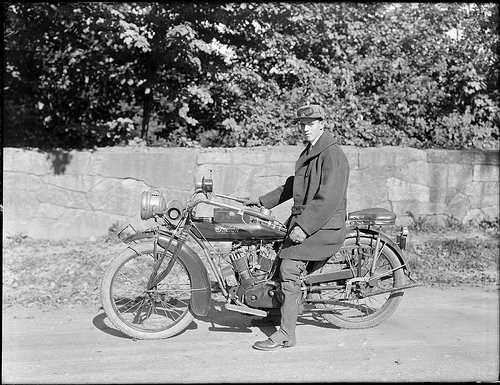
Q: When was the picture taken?
A: Daytime.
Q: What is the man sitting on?
A: A motorcycle.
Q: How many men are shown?
A: One.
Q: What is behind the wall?
A: Trees.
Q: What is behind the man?
A: A brick wall.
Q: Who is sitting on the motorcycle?
A: A man.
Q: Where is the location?
A: A park.